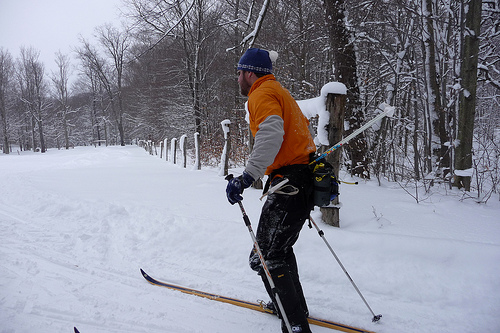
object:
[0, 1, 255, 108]
sky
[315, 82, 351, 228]
post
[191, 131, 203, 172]
post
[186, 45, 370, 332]
skier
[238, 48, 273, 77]
hat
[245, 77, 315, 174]
sweater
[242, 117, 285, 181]
sleeve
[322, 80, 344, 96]
snow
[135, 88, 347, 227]
fence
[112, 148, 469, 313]
snow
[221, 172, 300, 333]
ski pole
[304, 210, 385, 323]
ski pole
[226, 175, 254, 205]
glove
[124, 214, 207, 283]
footprints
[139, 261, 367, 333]
ski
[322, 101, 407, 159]
pick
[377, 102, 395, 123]
ice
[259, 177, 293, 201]
handle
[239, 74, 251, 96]
beard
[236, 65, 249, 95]
face